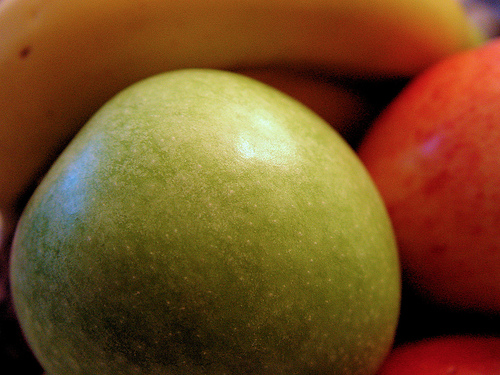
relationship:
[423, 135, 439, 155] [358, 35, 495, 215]
light shining on apple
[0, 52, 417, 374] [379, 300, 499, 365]
apple by apple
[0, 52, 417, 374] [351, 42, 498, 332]
apple by apple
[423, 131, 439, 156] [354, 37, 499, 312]
light shining on apple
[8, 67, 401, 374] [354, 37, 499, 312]
apple on apple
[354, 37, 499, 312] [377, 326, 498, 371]
apple on fruit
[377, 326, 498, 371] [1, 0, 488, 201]
fruit on fruit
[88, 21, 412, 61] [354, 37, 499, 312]
banana on apple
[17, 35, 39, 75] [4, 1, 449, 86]
black spot on banana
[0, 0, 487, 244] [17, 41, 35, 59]
banana has a black spot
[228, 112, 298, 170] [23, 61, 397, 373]
light on apple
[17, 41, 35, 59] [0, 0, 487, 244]
black spot on banana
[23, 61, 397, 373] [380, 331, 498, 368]
apple on top apple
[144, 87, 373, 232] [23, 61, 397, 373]
light on apple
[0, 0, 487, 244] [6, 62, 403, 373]
banana behind apples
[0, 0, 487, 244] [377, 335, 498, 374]
banana behind fruit